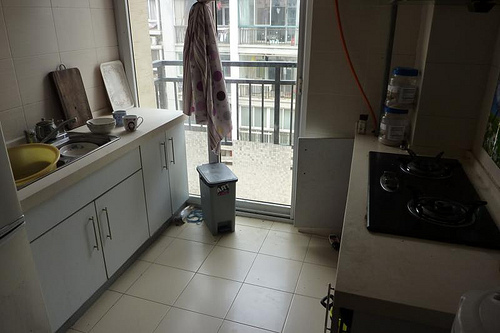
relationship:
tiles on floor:
[153, 249, 306, 321] [57, 204, 338, 331]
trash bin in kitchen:
[196, 161, 238, 237] [0, 0, 495, 328]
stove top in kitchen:
[350, 118, 492, 273] [0, 0, 495, 328]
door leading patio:
[137, 0, 300, 214] [231, 132, 296, 200]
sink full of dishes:
[6, 111, 161, 302] [57, 135, 102, 160]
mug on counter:
[123, 114, 142, 131] [137, 108, 179, 130]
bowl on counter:
[86, 117, 115, 135] [82, 102, 187, 156]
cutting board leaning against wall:
[49, 65, 92, 130] [2, 3, 148, 145]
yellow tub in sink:
[2, 142, 62, 185] [10, 125, 118, 192]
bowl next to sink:
[70, 110, 131, 141] [49, 135, 112, 164]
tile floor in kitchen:
[75, 194, 333, 329] [0, 0, 495, 328]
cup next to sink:
[111, 107, 127, 129] [4, 127, 124, 190]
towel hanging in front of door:
[180, 0, 232, 157] [147, 0, 298, 224]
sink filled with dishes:
[9, 131, 120, 193] [3, 89, 129, 196]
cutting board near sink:
[49, 64, 95, 130] [3, 124, 121, 194]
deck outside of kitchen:
[149, 56, 296, 212] [0, 0, 495, 328]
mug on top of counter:
[122, 115, 144, 132] [5, 107, 182, 197]